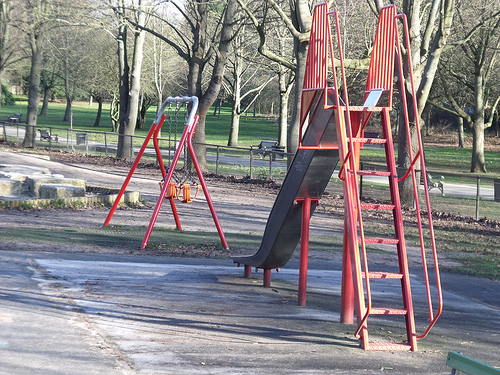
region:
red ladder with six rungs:
[335, 97, 430, 339]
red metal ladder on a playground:
[330, 101, 436, 350]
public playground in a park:
[96, 2, 456, 359]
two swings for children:
[93, 83, 229, 266]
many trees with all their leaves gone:
[18, 2, 488, 131]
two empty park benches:
[0, 105, 65, 145]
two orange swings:
[155, 168, 207, 209]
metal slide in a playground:
[228, 9, 417, 337]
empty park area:
[31, 91, 293, 161]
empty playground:
[82, 0, 449, 357]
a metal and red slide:
[228, 4, 470, 359]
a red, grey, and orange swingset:
[97, 85, 246, 255]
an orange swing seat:
[173, 181, 204, 206]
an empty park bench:
[248, 132, 283, 162]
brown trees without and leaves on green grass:
[0, 1, 150, 122]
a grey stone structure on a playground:
[0, 165, 151, 212]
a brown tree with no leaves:
[438, 2, 493, 176]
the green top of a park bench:
[437, 345, 499, 374]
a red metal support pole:
[291, 191, 323, 307]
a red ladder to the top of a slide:
[336, 106, 441, 360]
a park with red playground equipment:
[90, 13, 495, 365]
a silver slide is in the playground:
[232, 5, 442, 350]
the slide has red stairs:
[332, 101, 417, 351]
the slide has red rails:
[301, 1, 441, 338]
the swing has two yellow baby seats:
[96, 95, 231, 256]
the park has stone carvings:
[5, 167, 142, 217]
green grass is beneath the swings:
[98, 95, 233, 256]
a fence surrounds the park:
[2, 118, 497, 248]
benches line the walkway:
[0, 116, 496, 202]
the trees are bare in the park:
[5, 2, 497, 188]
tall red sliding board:
[224, 1, 469, 349]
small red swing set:
[94, 93, 252, 252]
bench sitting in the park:
[249, 139, 281, 156]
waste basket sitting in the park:
[75, 131, 85, 143]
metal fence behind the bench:
[0, 121, 497, 226]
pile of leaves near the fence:
[0, 150, 496, 220]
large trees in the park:
[0, 0, 495, 175]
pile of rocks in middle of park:
[0, 160, 92, 196]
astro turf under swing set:
[1, 231, 278, 244]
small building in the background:
[3, 75, 35, 95]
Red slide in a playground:
[230, 2, 444, 355]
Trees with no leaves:
[112, 1, 269, 100]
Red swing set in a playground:
[100, 82, 234, 259]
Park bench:
[218, 132, 289, 167]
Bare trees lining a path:
[6, 0, 305, 118]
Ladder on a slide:
[329, 99, 441, 371]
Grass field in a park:
[10, 82, 157, 143]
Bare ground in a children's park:
[11, 233, 87, 370]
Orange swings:
[157, 176, 203, 206]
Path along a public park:
[7, 114, 276, 189]